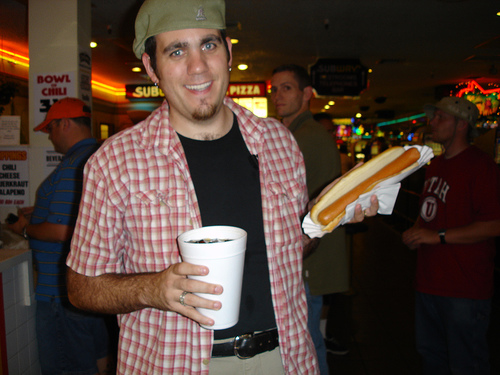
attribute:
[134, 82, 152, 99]
u — letter 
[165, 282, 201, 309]
band — wedding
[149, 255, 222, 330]
hand — man's 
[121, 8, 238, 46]
hat — green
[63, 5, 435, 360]
man — standing in line, black watch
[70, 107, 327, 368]
shirt — black , checkered ,  red plaid 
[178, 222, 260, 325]
cup — ice, Soda 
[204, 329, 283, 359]
belt — black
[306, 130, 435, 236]
hotdog — long bun, large 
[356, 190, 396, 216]
towel — White paper 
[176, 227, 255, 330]
cup — large white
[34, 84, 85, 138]
hat — red 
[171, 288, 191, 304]
ring — wedding  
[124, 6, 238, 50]
hat — tan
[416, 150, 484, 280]
shirt — red tee 